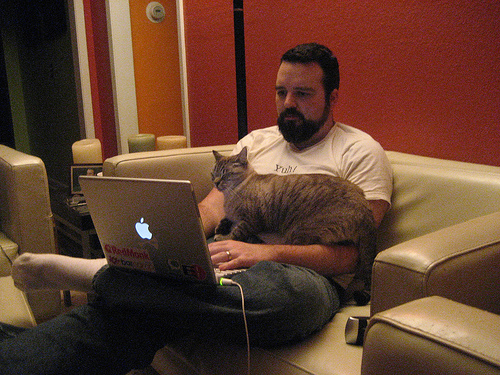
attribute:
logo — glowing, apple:
[133, 216, 152, 242]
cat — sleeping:
[208, 146, 379, 304]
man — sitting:
[1, 41, 393, 375]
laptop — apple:
[78, 174, 249, 289]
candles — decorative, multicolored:
[70, 134, 189, 165]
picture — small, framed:
[67, 163, 103, 194]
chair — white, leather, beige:
[101, 146, 499, 375]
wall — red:
[73, 2, 499, 167]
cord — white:
[218, 276, 250, 375]